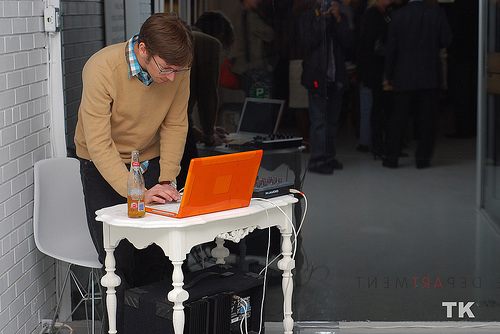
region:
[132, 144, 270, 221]
plastic laptop computer colored orange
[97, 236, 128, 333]
white table leg with ornate scrolling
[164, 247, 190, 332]
white table leg with ornate scrolling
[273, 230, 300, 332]
white table leg with ornate scrolling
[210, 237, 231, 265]
white table leg with ornate scrolling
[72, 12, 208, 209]
person wearing a brown sweater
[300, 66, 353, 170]
pair of blue jeans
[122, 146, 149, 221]
glass bottle with liquid in the bottom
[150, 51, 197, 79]
pair of black eye glasses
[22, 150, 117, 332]
chair with white plastic seat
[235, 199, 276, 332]
white cord leading down from the table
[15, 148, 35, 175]
brick in the wall painted white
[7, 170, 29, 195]
brick in the wall painted white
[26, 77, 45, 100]
brick in the wall painted white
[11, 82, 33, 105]
brick in the wall painted white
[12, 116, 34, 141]
brick in the wall painted white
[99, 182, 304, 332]
a white table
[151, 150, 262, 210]
an orange laptop on the desk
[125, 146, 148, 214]
a bottle on the table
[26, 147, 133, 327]
a white chair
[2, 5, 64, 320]
a white brick wall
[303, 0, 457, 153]
people standing in the building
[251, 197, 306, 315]
cords connected to the laptop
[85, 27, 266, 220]
a man looking at a laptop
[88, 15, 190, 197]
a man in a brown sweater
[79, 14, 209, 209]
a man who is wearing glasses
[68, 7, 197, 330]
This is a person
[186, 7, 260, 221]
This is a person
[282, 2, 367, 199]
This is a person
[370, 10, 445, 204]
This is a person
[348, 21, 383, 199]
This is a person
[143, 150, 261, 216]
an orange laptop on a desk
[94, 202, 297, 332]
a white desk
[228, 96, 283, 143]
a white laptop on a desk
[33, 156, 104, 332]
a white plastic chair with metal legs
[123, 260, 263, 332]
a black suitcase underneath a desk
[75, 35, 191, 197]
man wearing a light brown sweater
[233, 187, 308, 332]
white plugs and wires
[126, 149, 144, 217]
a juice bottle on a desk